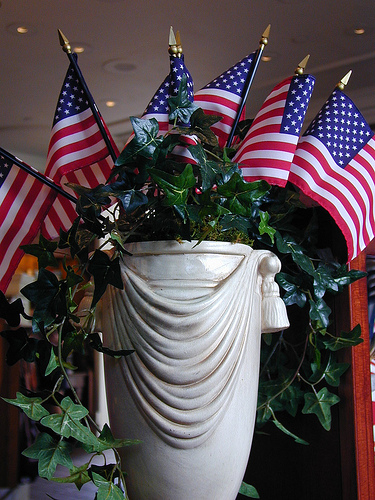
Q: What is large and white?
A: The planter.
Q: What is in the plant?
A: American flag.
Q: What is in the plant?
A: American flag.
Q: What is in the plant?
A: American flag.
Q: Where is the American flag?
A: Plant.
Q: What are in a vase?
A: American flags.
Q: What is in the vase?
A: Green leaves and flags.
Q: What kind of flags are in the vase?
A: American flags.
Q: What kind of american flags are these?
A: Mini flags.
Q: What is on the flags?
A: Stars and stripes.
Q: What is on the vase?
A: Chiseled drape design and tassles.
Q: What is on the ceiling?
A: Recessed round lighting.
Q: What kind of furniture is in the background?
A: Dark wood furniture.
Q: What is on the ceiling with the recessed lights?
A: Round speaker on ceiling.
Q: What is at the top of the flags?
A: Triangular plastic point.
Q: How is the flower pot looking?
A: White.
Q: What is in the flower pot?
A: Vine.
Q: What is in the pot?
A: Vine.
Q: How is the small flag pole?
A: Gold.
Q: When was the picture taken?
A: Daytime.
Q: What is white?
A: Pot.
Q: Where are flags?
A: In a pot.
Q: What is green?
A: Leaves.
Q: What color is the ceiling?
A: White.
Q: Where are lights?
A: On the ceiling.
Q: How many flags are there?
A: Six.